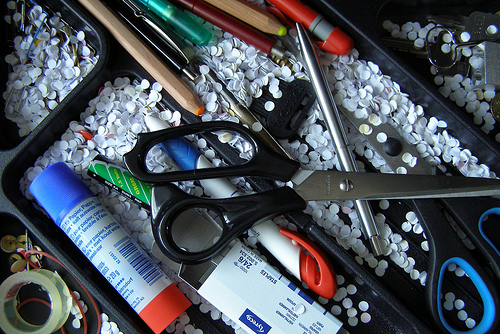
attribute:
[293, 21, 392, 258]
pen — silver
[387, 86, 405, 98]
paper — white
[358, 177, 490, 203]
blade — silver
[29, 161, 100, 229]
cap — blue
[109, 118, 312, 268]
handle — black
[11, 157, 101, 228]
cap — blue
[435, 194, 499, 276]
handle — black, blue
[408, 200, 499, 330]
handle — black, blue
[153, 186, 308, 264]
handle — black, blue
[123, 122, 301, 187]
handle — black, blue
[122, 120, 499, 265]
scissors/black handles — black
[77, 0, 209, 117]
pencil —  orange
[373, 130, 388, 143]
dot — white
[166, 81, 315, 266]
handle — black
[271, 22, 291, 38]
tip — yellow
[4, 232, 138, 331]
rubber bands — thin, red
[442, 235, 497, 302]
handle — black, blue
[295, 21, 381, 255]
pen — silver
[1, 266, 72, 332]
tape —  clear,  in roll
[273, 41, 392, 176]
pen — silver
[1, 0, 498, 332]
dots — paper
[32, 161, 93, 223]
cap — blue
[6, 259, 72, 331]
tape — clear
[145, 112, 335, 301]
pen — ink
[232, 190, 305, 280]
barrel — white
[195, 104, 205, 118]
tip — orange